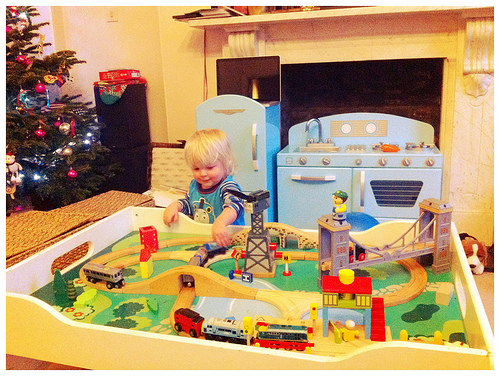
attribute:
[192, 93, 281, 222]
chair — white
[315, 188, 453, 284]
toy bridge — wooden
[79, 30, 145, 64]
wall — white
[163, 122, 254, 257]
child — small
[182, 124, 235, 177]
hair — blonde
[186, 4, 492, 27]
mantle — white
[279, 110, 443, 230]
sink — toy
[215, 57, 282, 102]
computer monitor — black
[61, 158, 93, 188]
ball — red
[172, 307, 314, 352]
train — toy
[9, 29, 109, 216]
tree — decorated, Christmas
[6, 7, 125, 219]
tree — Christmas, lights-decorated, ornament-decorated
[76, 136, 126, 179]
leaves — green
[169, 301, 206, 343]
caboose — red, wooden